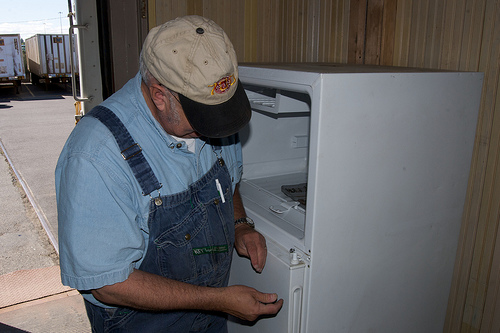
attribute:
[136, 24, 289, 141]
hat — tan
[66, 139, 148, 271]
shirt — blue, short sleeved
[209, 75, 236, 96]
logo — red, yellow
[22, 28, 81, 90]
truck — large, semi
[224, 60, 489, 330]
refrigerator — tall, white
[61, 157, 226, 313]
arm — hairy, fair pale skin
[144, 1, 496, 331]
wall — wood paneled, different shades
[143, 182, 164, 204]
buckle — metallic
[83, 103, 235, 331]
overalls — denim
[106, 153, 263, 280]
overalls — denim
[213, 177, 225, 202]
pen — white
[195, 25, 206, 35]
tip — black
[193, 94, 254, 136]
bill — black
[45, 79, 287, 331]
overalls — denim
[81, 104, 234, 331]
overall — denim 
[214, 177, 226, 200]
pen — white 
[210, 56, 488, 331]
freezer — white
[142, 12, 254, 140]
hat — yellow, light brown, beige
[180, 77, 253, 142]
brim — black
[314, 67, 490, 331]
fridge side — white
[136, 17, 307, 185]
cap — tan, black, baseball cap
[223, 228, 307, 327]
refrigerator door — white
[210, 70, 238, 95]
logo — red